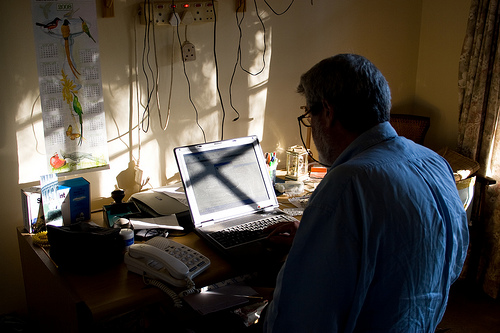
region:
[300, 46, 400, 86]
man has dark hair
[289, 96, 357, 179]
man is wearing glasses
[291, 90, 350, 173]
strap hanging from glasses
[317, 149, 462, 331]
man has blue shirt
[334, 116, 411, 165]
blue shirt is collared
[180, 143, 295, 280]
man is holding laptop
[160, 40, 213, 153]
tan wall behind man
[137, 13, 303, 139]
numerous cords hanging from power strip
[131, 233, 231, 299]
white phone next to man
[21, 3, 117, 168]
large bird themed calendar on wall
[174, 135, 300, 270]
the opened laptop on the desk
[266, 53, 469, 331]
the man sitting in front of the laptop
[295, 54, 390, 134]
the hair on the man's head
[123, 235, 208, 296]
the phone on the desk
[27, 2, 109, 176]
the calendar on the wall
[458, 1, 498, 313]
the curtain hanging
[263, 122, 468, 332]
the shirt on the man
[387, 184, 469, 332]
the wrinkles on the back of the man's shirt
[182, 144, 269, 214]
the screen on the laptop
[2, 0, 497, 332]
the sun shining into the room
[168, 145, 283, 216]
window casts shadow on a laptop screen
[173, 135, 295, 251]
an open laptop on a desk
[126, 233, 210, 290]
a white desk phone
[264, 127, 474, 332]
man wears a blue collared shirt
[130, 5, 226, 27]
power strip hung on the wall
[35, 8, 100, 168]
a poster about birds and butterflies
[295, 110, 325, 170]
eyeglasses with a neck cord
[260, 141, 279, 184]
holder for pens and pencils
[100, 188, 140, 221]
a rubber stamp in a holder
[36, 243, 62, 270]
a pencil wedged in a corner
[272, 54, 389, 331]
senior citizen sitting at laptop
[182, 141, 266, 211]
shadows cast across laptop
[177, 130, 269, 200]
light shining in on laptop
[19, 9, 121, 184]
calender on wall on left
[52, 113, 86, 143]
butterfly on calender on wall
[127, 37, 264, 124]
black cables hanging from ceiling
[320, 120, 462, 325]
blue shirt on man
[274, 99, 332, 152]
eyeglasses on man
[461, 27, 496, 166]
curtains on right wall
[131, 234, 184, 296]
white phone on desk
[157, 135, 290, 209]
bold black cross on computer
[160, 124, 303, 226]
wide silver computer screen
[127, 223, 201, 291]
white land line telephone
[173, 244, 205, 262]
big button on telephone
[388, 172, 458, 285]
wrinkles at back of blue shirt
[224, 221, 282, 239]
computer's white key board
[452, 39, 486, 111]
green and white drapes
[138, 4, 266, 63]
many wall plugs on the wall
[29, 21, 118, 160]
birds on white calendar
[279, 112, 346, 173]
string on eye glasses